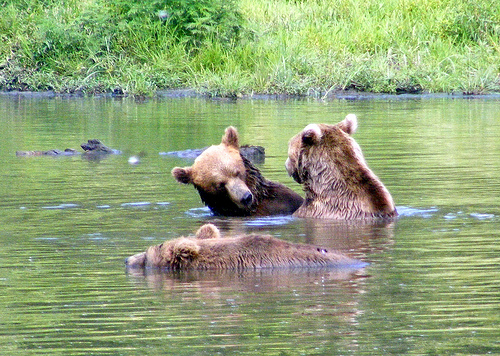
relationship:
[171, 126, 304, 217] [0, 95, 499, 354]
bear in water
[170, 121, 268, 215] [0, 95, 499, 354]
head sticking out water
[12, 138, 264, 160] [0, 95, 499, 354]
rocks sticking out water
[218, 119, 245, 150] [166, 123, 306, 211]
ear sticking off head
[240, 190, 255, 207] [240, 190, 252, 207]
nose on nose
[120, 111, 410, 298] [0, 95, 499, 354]
three bears in water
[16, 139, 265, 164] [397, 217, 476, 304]
rocks in water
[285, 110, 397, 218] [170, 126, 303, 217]
bear next to bear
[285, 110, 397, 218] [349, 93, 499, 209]
bear in water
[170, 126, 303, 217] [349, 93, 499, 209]
bear in water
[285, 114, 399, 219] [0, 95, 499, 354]
bear in water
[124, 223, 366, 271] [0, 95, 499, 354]
bear in water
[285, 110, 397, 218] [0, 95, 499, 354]
bear in water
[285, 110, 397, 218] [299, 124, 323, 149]
bear has ear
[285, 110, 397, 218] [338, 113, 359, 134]
bear has ear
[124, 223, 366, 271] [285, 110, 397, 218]
bear with bear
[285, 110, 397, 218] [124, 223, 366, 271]
bear with bear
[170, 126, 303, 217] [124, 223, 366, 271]
bear with bear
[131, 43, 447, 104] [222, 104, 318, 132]
bank on water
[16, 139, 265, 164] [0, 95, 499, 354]
rocks on water